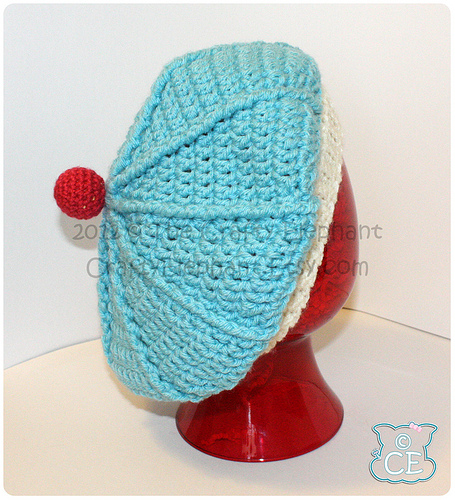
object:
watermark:
[66, 216, 390, 284]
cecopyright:
[365, 416, 444, 494]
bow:
[407, 420, 420, 430]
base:
[171, 336, 349, 469]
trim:
[314, 75, 347, 302]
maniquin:
[37, 30, 382, 473]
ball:
[51, 165, 108, 223]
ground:
[314, 98, 346, 161]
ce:
[382, 449, 424, 476]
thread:
[144, 110, 286, 266]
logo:
[364, 419, 440, 488]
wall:
[56, 55, 124, 122]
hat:
[46, 37, 356, 413]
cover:
[46, 36, 351, 411]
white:
[257, 80, 348, 370]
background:
[2, 3, 455, 500]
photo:
[4, 7, 441, 496]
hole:
[210, 257, 225, 271]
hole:
[163, 228, 181, 245]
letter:
[381, 449, 406, 478]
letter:
[402, 449, 425, 478]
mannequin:
[172, 150, 364, 468]